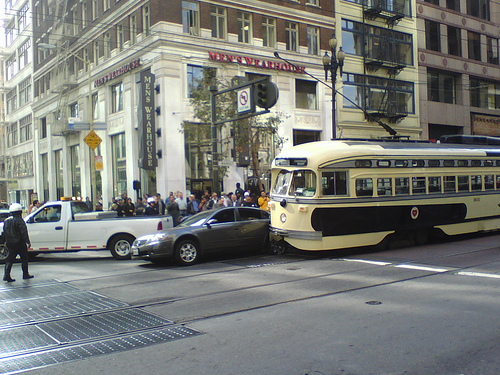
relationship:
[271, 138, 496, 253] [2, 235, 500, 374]
trolley on street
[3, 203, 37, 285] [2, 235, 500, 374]
officer on street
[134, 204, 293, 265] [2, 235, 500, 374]
car on street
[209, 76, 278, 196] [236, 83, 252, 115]
pole has sign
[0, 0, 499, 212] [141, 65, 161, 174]
building has sign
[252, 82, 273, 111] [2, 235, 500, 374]
lights above street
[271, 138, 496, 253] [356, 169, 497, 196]
trolley has windows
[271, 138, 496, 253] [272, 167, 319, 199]
trolley has windows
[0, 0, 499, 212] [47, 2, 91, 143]
building has fire escape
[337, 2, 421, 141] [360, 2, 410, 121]
building has fire escape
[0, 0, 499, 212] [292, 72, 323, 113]
building has a window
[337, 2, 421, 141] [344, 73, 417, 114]
building has a window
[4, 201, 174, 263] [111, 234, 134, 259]
truck has a tire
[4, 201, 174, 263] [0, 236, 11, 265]
truck has a tire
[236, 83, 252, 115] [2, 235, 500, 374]
sign on street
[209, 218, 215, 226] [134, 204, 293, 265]
mirror on car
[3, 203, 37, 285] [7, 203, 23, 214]
officer wearing helmet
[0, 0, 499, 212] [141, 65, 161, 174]
building has a sign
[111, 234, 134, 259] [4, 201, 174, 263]
tire on truck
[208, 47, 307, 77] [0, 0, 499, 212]
sign on a building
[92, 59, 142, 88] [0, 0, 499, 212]
sign on a building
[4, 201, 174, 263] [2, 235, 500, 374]
truck on street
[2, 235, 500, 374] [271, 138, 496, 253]
tracks for trolley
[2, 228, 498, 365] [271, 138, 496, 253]
tracks for a trolley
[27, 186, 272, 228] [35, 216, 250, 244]
pedestrians on sidewalks